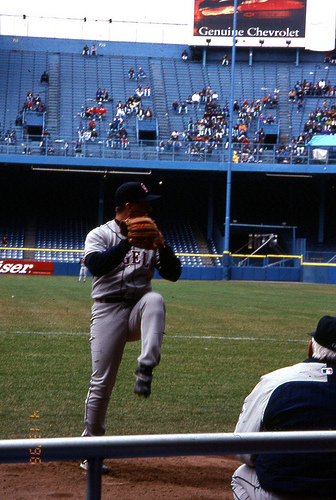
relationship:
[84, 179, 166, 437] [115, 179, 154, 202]
man wearing hat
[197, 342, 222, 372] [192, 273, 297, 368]
grass in field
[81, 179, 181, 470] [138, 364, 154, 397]
man wearing sneakers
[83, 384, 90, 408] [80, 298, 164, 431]
stripe on pants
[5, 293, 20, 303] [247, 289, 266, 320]
ball on grass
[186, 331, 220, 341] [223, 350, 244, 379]
line on grass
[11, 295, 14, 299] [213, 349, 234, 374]
ball on grass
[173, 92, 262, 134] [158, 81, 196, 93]
people watching at bench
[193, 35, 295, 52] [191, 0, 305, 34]
lights below screen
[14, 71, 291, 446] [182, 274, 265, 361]
photo of a field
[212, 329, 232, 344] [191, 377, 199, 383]
line on ground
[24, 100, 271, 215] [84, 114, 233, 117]
stadium has people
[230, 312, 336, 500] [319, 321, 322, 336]
man has cap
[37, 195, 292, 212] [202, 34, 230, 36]
stadium has billboard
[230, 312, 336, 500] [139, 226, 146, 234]
man has ball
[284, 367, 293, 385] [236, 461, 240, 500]
man crouched on knees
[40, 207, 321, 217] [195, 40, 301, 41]
stadium has lights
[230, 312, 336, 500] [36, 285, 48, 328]
man at field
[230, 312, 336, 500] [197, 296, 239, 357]
man at field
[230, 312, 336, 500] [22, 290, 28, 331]
man at field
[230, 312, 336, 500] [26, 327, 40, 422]
man at field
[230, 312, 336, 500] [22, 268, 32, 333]
man at field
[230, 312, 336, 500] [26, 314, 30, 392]
man at field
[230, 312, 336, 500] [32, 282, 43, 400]
man at field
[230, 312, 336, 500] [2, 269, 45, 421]
man at field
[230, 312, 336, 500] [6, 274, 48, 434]
man at field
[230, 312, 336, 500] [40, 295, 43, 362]
man at field